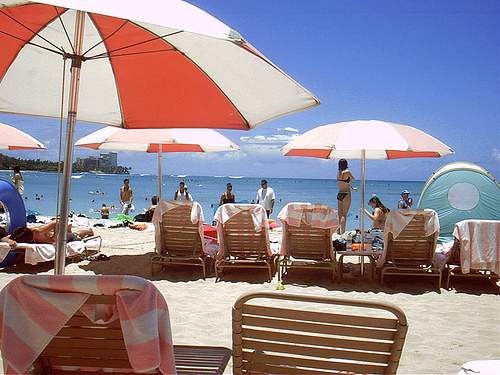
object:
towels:
[276, 201, 341, 262]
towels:
[430, 218, 499, 280]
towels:
[0, 239, 101, 266]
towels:
[149, 198, 219, 257]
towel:
[0, 273, 177, 374]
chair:
[148, 202, 215, 281]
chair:
[213, 203, 280, 282]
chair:
[277, 201, 339, 284]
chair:
[373, 208, 443, 291]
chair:
[432, 218, 499, 292]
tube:
[0, 177, 28, 239]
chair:
[0, 235, 103, 267]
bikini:
[333, 169, 353, 204]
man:
[395, 190, 412, 210]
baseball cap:
[397, 189, 410, 197]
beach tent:
[414, 159, 499, 244]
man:
[0, 221, 95, 249]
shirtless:
[0, 219, 60, 250]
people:
[34, 192, 42, 201]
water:
[0, 168, 429, 224]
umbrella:
[279, 119, 456, 278]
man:
[254, 178, 277, 218]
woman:
[334, 157, 359, 234]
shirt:
[254, 186, 274, 211]